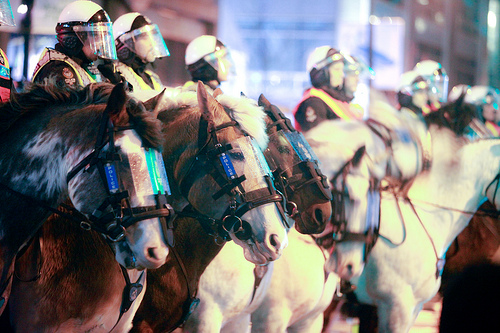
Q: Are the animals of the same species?
A: Yes, all the animals are horses.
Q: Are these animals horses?
A: Yes, all the animals are horses.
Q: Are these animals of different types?
A: No, all the animals are horses.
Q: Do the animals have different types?
A: No, all the animals are horses.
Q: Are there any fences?
A: No, there are no fences.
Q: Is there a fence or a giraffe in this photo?
A: No, there are no fences or giraffes.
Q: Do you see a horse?
A: Yes, there is a horse.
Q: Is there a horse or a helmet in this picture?
A: Yes, there is a horse.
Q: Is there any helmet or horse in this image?
A: Yes, there is a horse.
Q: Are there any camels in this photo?
A: No, there are no camels.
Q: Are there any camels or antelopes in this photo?
A: No, there are no camels or antelopes.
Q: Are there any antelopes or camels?
A: No, there are no camels or antelopes.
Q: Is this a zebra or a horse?
A: This is a horse.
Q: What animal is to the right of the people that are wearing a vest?
A: The animal is a horse.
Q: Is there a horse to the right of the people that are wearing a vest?
A: Yes, there is a horse to the right of the people.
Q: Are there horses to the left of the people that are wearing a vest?
A: No, the horse is to the right of the people.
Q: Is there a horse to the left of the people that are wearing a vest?
A: No, the horse is to the right of the people.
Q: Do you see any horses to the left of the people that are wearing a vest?
A: No, the horse is to the right of the people.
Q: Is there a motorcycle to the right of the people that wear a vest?
A: No, there is a horse to the right of the people.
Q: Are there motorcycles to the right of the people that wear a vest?
A: No, there is a horse to the right of the people.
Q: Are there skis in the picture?
A: No, there are no skis.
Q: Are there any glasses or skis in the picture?
A: No, there are no skis or glasses.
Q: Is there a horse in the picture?
A: Yes, there is a horse.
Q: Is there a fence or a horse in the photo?
A: Yes, there is a horse.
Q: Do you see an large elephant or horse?
A: Yes, there is a large horse.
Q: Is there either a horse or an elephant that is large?
A: Yes, the horse is large.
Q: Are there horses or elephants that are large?
A: Yes, the horse is large.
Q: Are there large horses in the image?
A: Yes, there is a large horse.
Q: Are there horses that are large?
A: Yes, there is a horse that is large.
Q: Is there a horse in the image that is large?
A: Yes, there is a horse that is large.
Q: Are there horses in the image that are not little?
A: Yes, there is a large horse.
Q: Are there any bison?
A: No, there are no bison.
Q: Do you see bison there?
A: No, there are no bison.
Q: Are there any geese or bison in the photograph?
A: No, there are no bison or geese.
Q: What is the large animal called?
A: The animal is a horse.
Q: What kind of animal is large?
A: The animal is a horse.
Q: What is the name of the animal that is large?
A: The animal is a horse.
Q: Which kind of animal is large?
A: The animal is a horse.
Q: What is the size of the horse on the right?
A: The horse is large.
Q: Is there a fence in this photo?
A: No, there are no fences.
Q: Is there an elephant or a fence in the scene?
A: No, there are no fences or elephants.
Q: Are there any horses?
A: Yes, there is a horse.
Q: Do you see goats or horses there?
A: Yes, there is a horse.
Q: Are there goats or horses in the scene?
A: Yes, there is a horse.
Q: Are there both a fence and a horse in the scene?
A: No, there is a horse but no fences.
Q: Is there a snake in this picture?
A: No, there are no snakes.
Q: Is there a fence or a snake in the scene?
A: No, there are no snakes or fences.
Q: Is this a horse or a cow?
A: This is a horse.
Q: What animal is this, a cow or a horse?
A: This is a horse.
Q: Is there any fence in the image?
A: No, there are no fences.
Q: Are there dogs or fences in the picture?
A: No, there are no fences or dogs.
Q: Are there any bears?
A: No, there are no bears.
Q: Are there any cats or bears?
A: No, there are no bears or cats.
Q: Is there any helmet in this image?
A: Yes, there is a helmet.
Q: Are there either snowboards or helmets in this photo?
A: Yes, there is a helmet.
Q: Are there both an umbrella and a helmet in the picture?
A: No, there is a helmet but no umbrellas.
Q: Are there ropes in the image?
A: No, there are no ropes.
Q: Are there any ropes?
A: No, there are no ropes.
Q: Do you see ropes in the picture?
A: No, there are no ropes.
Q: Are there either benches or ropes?
A: No, there are no ropes or benches.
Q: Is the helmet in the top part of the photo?
A: Yes, the helmet is in the top of the image.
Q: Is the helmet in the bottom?
A: No, the helmet is in the top of the image.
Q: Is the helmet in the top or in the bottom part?
A: The helmet is in the top of the image.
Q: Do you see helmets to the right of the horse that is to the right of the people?
A: Yes, there is a helmet to the right of the horse.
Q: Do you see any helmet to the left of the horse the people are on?
A: No, the helmet is to the right of the horse.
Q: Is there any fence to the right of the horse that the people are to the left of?
A: No, there is a helmet to the right of the horse.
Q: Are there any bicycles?
A: No, there are no bicycles.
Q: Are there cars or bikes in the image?
A: No, there are no bikes or cars.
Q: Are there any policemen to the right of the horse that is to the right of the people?
A: Yes, there is a policeman to the right of the horse.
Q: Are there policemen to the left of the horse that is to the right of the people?
A: No, the policeman is to the right of the horse.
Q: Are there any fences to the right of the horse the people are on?
A: No, there is a policeman to the right of the horse.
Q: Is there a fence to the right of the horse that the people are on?
A: No, there is a policeman to the right of the horse.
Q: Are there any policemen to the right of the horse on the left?
A: Yes, there is a policeman to the right of the horse.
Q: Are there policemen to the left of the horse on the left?
A: No, the policeman is to the right of the horse.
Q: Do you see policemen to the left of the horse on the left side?
A: No, the policeman is to the right of the horse.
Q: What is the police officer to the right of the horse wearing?
A: The police officer is wearing a helmet.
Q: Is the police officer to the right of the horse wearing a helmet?
A: Yes, the police officer is wearing a helmet.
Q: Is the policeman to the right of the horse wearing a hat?
A: No, the police officer is wearing a helmet.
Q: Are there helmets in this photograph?
A: Yes, there is a helmet.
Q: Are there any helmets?
A: Yes, there is a helmet.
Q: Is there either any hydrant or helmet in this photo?
A: Yes, there is a helmet.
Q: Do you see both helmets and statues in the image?
A: No, there is a helmet but no statues.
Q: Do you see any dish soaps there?
A: No, there are no dish soaps.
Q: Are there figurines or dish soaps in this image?
A: No, there are no dish soaps or figurines.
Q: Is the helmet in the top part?
A: Yes, the helmet is in the top of the image.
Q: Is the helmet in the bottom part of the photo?
A: No, the helmet is in the top of the image.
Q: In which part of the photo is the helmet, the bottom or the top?
A: The helmet is in the top of the image.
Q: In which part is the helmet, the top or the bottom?
A: The helmet is in the top of the image.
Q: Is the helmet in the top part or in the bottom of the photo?
A: The helmet is in the top of the image.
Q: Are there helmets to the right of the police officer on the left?
A: Yes, there is a helmet to the right of the policeman.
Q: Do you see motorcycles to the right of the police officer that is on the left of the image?
A: No, there is a helmet to the right of the policeman.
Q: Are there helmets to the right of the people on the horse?
A: Yes, there is a helmet to the right of the people.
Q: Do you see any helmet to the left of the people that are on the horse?
A: No, the helmet is to the right of the people.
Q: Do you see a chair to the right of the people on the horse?
A: No, there is a helmet to the right of the people.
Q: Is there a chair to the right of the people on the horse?
A: No, there is a helmet to the right of the people.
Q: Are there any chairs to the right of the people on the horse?
A: No, there is a helmet to the right of the people.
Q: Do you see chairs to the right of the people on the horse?
A: No, there is a helmet to the right of the people.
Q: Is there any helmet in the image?
A: Yes, there is a helmet.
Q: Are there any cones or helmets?
A: Yes, there is a helmet.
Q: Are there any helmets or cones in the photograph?
A: Yes, there is a helmet.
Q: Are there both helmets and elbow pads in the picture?
A: No, there is a helmet but no elbow pads.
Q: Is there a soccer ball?
A: No, there are no soccer balls.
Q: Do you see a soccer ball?
A: No, there are no soccer balls.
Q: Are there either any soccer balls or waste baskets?
A: No, there are no soccer balls or waste baskets.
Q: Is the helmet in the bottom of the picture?
A: No, the helmet is in the top of the image.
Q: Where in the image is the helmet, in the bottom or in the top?
A: The helmet is in the top of the image.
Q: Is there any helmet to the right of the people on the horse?
A: Yes, there is a helmet to the right of the people.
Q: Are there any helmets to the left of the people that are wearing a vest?
A: No, the helmet is to the right of the people.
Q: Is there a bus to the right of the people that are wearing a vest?
A: No, there is a helmet to the right of the people.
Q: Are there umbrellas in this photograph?
A: No, there are no umbrellas.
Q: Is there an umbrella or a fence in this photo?
A: No, there are no umbrellas or fences.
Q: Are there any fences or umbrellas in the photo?
A: No, there are no umbrellas or fences.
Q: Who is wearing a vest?
A: The people are wearing a vest.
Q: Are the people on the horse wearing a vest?
A: Yes, the people are wearing a vest.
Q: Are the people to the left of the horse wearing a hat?
A: No, the people are wearing a vest.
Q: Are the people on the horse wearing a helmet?
A: Yes, the people are wearing a helmet.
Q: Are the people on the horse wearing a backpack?
A: No, the people are wearing a helmet.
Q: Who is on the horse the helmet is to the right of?
A: The people are on the horse.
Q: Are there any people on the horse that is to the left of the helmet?
A: Yes, there are people on the horse.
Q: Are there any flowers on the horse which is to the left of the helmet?
A: No, there are people on the horse.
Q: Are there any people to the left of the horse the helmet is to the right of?
A: Yes, there are people to the left of the horse.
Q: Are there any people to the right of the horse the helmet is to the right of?
A: No, the people are to the left of the horse.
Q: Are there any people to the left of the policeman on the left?
A: Yes, there are people to the left of the policeman.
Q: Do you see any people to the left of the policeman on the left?
A: Yes, there are people to the left of the policeman.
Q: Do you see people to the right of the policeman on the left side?
A: No, the people are to the left of the police officer.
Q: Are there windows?
A: Yes, there is a window.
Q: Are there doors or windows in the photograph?
A: Yes, there is a window.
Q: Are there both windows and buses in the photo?
A: No, there is a window but no buses.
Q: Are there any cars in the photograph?
A: No, there are no cars.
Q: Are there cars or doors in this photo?
A: No, there are no cars or doors.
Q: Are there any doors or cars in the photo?
A: No, there are no cars or doors.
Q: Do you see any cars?
A: No, there are no cars.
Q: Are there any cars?
A: No, there are no cars.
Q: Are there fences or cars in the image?
A: No, there are no cars or fences.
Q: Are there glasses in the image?
A: No, there are no glasses.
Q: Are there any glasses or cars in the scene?
A: No, there are no glasses or cars.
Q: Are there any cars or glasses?
A: No, there are no glasses or cars.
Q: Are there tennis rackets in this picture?
A: No, there are no tennis rackets.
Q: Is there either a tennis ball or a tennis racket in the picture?
A: No, there are no rackets or tennis balls.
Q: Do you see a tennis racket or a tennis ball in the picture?
A: No, there are no rackets or tennis balls.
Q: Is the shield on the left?
A: Yes, the shield is on the left of the image.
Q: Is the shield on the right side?
A: No, the shield is on the left of the image.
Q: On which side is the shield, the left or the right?
A: The shield is on the left of the image.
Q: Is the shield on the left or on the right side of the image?
A: The shield is on the left of the image.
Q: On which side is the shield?
A: The shield is on the left of the image.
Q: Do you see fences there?
A: No, there are no fences.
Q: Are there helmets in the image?
A: Yes, there is a helmet.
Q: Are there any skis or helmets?
A: Yes, there is a helmet.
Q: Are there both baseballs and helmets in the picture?
A: No, there is a helmet but no baseballs.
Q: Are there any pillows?
A: No, there are no pillows.